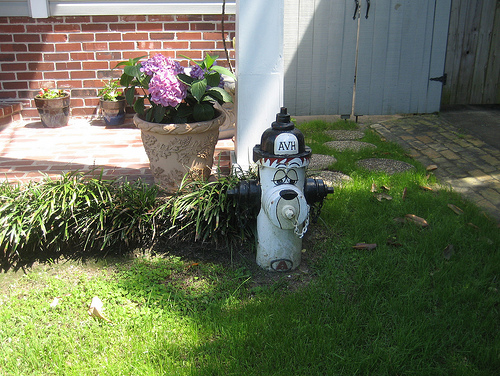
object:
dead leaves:
[370, 182, 391, 202]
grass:
[3, 169, 144, 257]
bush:
[0, 165, 258, 252]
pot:
[25, 86, 73, 128]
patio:
[8, 119, 493, 217]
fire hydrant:
[225, 105, 335, 273]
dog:
[256, 158, 308, 254]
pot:
[134, 106, 225, 192]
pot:
[134, 116, 219, 196]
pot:
[100, 97, 124, 120]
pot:
[34, 90, 69, 126]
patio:
[0, 117, 235, 184]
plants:
[95, 76, 120, 99]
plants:
[34, 87, 69, 98]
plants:
[114, 51, 234, 118]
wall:
[0, 14, 230, 130]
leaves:
[348, 173, 461, 258]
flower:
[138, 55, 185, 77]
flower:
[145, 68, 187, 106]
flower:
[186, 62, 222, 93]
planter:
[133, 112, 225, 192]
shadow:
[169, 158, 496, 372]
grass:
[150, 160, 265, 253]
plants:
[0, 167, 227, 251]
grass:
[173, 114, 493, 376]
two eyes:
[268, 169, 301, 185]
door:
[281, 0, 452, 118]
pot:
[139, 98, 219, 195]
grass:
[5, 264, 169, 355]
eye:
[271, 169, 287, 186]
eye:
[287, 169, 299, 185]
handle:
[353, 0, 361, 19]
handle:
[361, 0, 373, 20]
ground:
[0, 175, 498, 373]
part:
[7, 267, 196, 370]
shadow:
[199, 190, 498, 367]